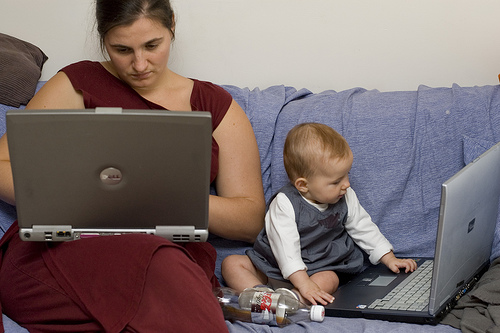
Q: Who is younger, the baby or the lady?
A: The baby is younger than the lady.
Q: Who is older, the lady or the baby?
A: The lady is older than the baby.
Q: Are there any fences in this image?
A: No, there are no fences.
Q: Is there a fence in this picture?
A: No, there are no fences.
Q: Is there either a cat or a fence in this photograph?
A: No, there are no fences or cats.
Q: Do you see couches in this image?
A: Yes, there is a couch.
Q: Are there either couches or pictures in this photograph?
A: Yes, there is a couch.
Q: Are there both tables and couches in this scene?
A: No, there is a couch but no tables.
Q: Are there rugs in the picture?
A: No, there are no rugs.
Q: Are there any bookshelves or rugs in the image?
A: No, there are no rugs or bookshelves.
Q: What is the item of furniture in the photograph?
A: The piece of furniture is a couch.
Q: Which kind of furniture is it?
A: The piece of furniture is a couch.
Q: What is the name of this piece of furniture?
A: This is a couch.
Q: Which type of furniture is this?
A: This is a couch.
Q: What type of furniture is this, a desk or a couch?
A: This is a couch.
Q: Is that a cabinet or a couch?
A: That is a couch.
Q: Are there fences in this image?
A: No, there are no fences.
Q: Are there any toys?
A: No, there are no toys.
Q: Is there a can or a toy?
A: No, there are no toys or cans.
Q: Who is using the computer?
A: The family is using the computer.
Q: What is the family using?
A: The family is using a computer.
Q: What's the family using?
A: The family is using a computer.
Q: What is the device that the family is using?
A: The device is a computer.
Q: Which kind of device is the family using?
A: The family is using a computer.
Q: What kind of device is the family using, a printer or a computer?
A: The family is using a computer.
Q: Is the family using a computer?
A: Yes, the family is using a computer.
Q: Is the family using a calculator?
A: No, the family is using a computer.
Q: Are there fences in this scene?
A: No, there are no fences.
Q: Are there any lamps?
A: No, there are no lamps.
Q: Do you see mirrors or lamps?
A: No, there are no lamps or mirrors.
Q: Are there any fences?
A: No, there are no fences.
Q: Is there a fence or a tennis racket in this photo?
A: No, there are no fences or rackets.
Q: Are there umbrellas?
A: No, there are no umbrellas.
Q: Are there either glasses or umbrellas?
A: No, there are no umbrellas or glasses.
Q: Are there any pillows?
A: Yes, there is a pillow.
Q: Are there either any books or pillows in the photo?
A: Yes, there is a pillow.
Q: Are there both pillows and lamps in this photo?
A: No, there is a pillow but no lamps.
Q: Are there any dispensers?
A: No, there are no dispensers.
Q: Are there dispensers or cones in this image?
A: No, there are no dispensers or cones.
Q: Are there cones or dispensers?
A: No, there are no dispensers or cones.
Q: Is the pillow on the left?
A: Yes, the pillow is on the left of the image.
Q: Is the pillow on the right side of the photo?
A: No, the pillow is on the left of the image.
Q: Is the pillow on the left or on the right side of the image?
A: The pillow is on the left of the image.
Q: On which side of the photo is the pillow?
A: The pillow is on the left of the image.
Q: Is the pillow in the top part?
A: Yes, the pillow is in the top of the image.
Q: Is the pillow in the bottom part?
A: No, the pillow is in the top of the image.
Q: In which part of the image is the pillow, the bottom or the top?
A: The pillow is in the top of the image.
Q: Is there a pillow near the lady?
A: Yes, there is a pillow near the lady.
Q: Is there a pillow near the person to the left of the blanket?
A: Yes, there is a pillow near the lady.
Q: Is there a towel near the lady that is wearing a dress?
A: No, there is a pillow near the lady.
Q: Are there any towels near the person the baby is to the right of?
A: No, there is a pillow near the lady.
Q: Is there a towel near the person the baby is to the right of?
A: No, there is a pillow near the lady.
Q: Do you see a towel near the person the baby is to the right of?
A: No, there is a pillow near the lady.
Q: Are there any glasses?
A: No, there are no glasses.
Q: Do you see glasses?
A: No, there are no glasses.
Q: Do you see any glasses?
A: No, there are no glasses.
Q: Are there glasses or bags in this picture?
A: No, there are no glasses or bags.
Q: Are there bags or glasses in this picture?
A: No, there are no glasses or bags.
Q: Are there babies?
A: Yes, there is a baby.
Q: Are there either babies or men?
A: Yes, there is a baby.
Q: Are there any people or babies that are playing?
A: Yes, the baby is playing.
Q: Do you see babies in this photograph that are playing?
A: Yes, there is a baby that is playing.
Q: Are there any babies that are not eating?
A: Yes, there is a baby that is playing.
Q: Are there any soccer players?
A: No, there are no soccer players.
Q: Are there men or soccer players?
A: No, there are no soccer players or men.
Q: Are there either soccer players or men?
A: No, there are no soccer players or men.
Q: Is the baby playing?
A: Yes, the baby is playing.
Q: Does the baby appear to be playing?
A: Yes, the baby is playing.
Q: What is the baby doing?
A: The baby is playing.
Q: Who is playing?
A: The baby is playing.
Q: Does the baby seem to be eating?
A: No, the baby is playing.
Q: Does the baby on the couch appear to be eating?
A: No, the baby is playing.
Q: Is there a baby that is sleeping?
A: No, there is a baby but he is playing.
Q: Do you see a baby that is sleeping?
A: No, there is a baby but he is playing.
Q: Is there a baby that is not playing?
A: No, there is a baby but he is playing.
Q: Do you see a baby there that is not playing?
A: No, there is a baby but he is playing.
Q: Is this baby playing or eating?
A: The baby is playing.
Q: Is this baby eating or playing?
A: The baby is playing.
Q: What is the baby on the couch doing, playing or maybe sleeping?
A: The baby is playing.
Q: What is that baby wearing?
A: The baby is wearing a dress.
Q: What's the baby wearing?
A: The baby is wearing a dress.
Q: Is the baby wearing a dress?
A: Yes, the baby is wearing a dress.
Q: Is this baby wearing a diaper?
A: No, the baby is wearing a dress.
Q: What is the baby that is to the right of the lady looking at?
A: The baby is looking at the computer.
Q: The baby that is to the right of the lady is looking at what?
A: The baby is looking at the computer.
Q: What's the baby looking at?
A: The baby is looking at the computer.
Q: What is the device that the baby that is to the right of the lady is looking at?
A: The device is a computer.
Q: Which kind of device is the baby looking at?
A: The baby is looking at the computer.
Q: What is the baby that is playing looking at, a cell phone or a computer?
A: The baby is looking at a computer.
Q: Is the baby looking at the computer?
A: Yes, the baby is looking at the computer.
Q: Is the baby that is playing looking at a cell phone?
A: No, the baby is looking at the computer.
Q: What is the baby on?
A: The baby is on the couch.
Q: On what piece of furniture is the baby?
A: The baby is on the couch.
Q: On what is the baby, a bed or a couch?
A: The baby is on a couch.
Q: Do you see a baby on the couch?
A: Yes, there is a baby on the couch.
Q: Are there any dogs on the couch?
A: No, there is a baby on the couch.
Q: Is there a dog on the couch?
A: No, there is a baby on the couch.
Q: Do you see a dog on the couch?
A: No, there is a baby on the couch.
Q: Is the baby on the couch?
A: Yes, the baby is on the couch.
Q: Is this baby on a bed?
A: No, the baby is on the couch.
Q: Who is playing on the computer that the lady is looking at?
A: The baby is playing on the computer.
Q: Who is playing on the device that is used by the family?
A: The baby is playing on the computer.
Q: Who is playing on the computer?
A: The baby is playing on the computer.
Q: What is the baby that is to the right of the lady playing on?
A: The baby is playing on the computer.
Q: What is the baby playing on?
A: The baby is playing on the computer.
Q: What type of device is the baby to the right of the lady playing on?
A: The baby is playing on the computer.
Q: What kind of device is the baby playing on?
A: The baby is playing on the computer.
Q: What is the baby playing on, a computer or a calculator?
A: The baby is playing on a computer.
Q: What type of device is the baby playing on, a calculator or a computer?
A: The baby is playing on a computer.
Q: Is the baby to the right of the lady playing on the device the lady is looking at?
A: Yes, the baby is playing on the computer.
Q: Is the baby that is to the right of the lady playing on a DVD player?
A: No, the baby is playing on the computer.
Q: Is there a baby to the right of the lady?
A: Yes, there is a baby to the right of the lady.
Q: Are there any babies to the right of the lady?
A: Yes, there is a baby to the right of the lady.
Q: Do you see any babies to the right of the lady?
A: Yes, there is a baby to the right of the lady.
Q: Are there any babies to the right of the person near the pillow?
A: Yes, there is a baby to the right of the lady.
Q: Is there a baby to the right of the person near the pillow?
A: Yes, there is a baby to the right of the lady.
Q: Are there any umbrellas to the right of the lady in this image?
A: No, there is a baby to the right of the lady.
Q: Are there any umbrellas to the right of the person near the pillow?
A: No, there is a baby to the right of the lady.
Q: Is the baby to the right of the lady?
A: Yes, the baby is to the right of the lady.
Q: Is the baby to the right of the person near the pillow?
A: Yes, the baby is to the right of the lady.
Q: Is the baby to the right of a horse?
A: No, the baby is to the right of the lady.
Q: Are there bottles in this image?
A: Yes, there is a bottle.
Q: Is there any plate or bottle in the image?
A: Yes, there is a bottle.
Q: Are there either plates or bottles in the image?
A: Yes, there is a bottle.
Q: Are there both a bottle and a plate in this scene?
A: No, there is a bottle but no plates.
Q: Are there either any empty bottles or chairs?
A: Yes, there is an empty bottle.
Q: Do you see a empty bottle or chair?
A: Yes, there is an empty bottle.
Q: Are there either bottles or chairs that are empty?
A: Yes, the bottle is empty.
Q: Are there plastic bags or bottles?
A: Yes, there is a plastic bottle.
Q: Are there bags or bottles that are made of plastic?
A: Yes, the bottle is made of plastic.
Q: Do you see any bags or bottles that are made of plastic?
A: Yes, the bottle is made of plastic.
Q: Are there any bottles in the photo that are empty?
A: Yes, there is an empty bottle.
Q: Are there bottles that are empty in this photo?
A: Yes, there is an empty bottle.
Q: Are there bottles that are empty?
A: Yes, there is a bottle that is empty.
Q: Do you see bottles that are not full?
A: Yes, there is a empty bottle.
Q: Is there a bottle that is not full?
A: Yes, there is a empty bottle.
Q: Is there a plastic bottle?
A: Yes, there is a bottle that is made of plastic.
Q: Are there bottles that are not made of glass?
A: Yes, there is a bottle that is made of plastic.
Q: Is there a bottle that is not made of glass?
A: Yes, there is a bottle that is made of plastic.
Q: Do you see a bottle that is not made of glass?
A: Yes, there is a bottle that is made of plastic.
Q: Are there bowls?
A: No, there are no bowls.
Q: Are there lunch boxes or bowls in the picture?
A: No, there are no bowls or lunch boxes.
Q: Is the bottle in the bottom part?
A: Yes, the bottle is in the bottom of the image.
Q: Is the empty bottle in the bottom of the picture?
A: Yes, the bottle is in the bottom of the image.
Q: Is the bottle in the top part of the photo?
A: No, the bottle is in the bottom of the image.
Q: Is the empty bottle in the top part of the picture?
A: No, the bottle is in the bottom of the image.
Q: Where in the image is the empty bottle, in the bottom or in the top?
A: The bottle is in the bottom of the image.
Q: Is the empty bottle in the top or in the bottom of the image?
A: The bottle is in the bottom of the image.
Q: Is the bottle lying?
A: Yes, the bottle is lying.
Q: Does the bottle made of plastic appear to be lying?
A: Yes, the bottle is lying.